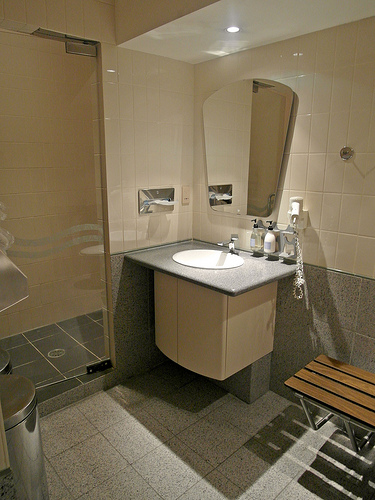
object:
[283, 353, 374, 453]
bench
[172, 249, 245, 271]
sink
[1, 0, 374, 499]
bathroom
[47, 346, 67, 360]
drain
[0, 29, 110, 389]
shower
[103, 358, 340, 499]
shadows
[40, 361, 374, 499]
ground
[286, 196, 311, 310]
hairdryer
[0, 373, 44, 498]
garbage can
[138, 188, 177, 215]
paper tower dispense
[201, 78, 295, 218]
mirror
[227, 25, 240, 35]
light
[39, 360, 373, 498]
tile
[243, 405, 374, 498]
shadow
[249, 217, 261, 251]
soap dispenser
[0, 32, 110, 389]
glass door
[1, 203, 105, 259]
etching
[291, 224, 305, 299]
cord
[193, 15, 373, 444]
wall